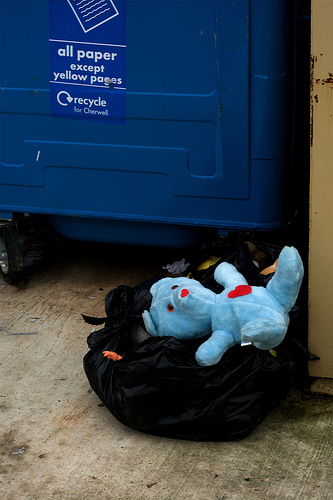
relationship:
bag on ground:
[75, 239, 315, 441] [2, 251, 330, 497]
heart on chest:
[228, 282, 252, 299] [211, 289, 236, 329]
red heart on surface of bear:
[223, 279, 254, 301] [141, 244, 303, 369]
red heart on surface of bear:
[178, 287, 191, 299] [141, 244, 303, 369]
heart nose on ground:
[180, 292, 188, 303] [0, 234, 332, 499]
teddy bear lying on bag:
[140, 235, 305, 368] [78, 261, 312, 442]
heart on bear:
[226, 282, 252, 299] [139, 243, 303, 368]